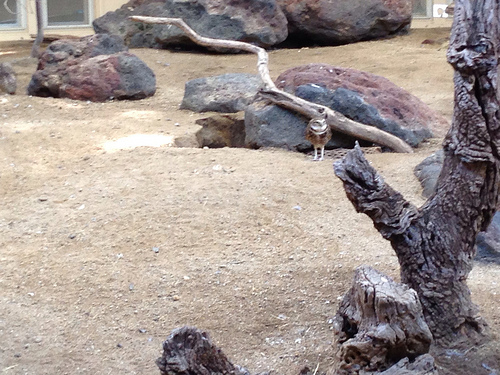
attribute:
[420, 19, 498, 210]
tree — rough, black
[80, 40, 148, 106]
rock — gray, brown, black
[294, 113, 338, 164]
owl — white, brown, small, black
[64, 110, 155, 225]
dirt — brown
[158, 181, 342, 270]
ground — dirty, dirt